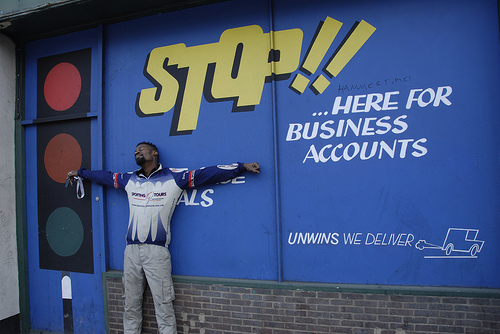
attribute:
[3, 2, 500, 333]
wall — blue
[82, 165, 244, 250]
shirt — white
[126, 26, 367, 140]
word — yellow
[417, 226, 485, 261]
truck — stick drawing, white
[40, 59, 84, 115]
circle — red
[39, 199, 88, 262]
circle — blue